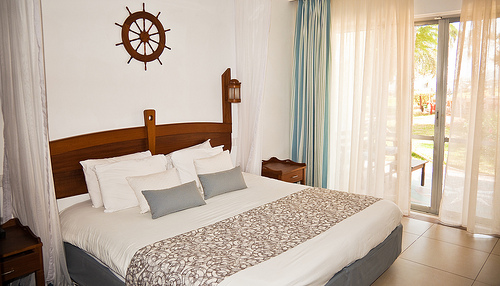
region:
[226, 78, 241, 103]
a wooden lantern attached to a bed post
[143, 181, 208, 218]
a gray cushion on a bed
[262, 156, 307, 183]
a wooden night table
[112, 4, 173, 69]
a wooden nautical wheel on a white wall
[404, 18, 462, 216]
a metal patio door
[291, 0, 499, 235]
blue and white curtains on the window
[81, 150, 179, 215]
white pillows on a bed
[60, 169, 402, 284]
a white bed-cover on a bed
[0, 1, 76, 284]
a white net next to a bed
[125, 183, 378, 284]
a gray and white throw on a bed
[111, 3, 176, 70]
wheel on the wall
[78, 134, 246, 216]
pillows on the bed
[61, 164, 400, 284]
a comforter on the bed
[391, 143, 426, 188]
a chair on the patio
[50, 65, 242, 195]
a wooden headboard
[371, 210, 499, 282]
off white tile floors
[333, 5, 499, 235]
white sheer curtains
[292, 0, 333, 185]
blue shimmer curtains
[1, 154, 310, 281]
the night stands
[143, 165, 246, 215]
grey pillows on the bed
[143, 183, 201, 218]
Small grey pillow on the bed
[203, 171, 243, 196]
Small grey pillow on the bed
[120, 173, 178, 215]
Small White pillow on the bed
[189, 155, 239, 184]
Small White pillow on the bed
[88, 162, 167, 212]
Small White pillow on the bed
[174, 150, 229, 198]
Small White pillow on the bed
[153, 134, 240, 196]
Small White pillow on the bed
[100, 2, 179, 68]
Large nautical decoration hanging on the wall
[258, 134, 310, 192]
Small wooden night stand with one drawer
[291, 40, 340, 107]
blue and white drapes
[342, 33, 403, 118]
sheer white drapes at door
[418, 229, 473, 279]
white tiles on floor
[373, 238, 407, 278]
blue covering on box spring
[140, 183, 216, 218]
small blue pillow on bed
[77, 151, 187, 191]
many white pillows on bed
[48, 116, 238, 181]
dark brown bed frame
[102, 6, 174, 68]
round brown anchor on wall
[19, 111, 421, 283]
large bed in the room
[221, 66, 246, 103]
small lamp on bed frame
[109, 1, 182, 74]
ship wheel on the wall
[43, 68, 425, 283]
bed is made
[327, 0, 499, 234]
sheer white curtains on the window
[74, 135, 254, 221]
pillows propped up on the bed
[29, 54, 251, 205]
wooden headboard against the wall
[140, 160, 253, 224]
two small gray pillows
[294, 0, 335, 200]
blue curtains pushed to one side of the window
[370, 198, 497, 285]
tile on the floor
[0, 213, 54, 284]
small brown table by the bed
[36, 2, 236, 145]
white paint on the wall